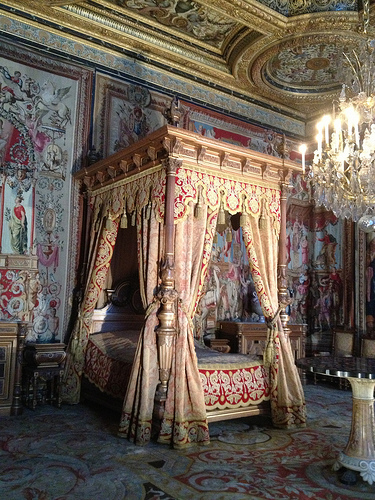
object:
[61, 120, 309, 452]
bed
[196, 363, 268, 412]
comforter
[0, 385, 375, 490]
floor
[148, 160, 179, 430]
pole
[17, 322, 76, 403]
table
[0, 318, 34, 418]
desk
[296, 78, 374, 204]
chandelier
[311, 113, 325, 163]
lights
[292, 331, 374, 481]
table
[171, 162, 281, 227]
canopy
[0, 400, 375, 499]
carpet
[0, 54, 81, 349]
wall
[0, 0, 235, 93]
trim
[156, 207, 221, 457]
drapes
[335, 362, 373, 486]
column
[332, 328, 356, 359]
cushions